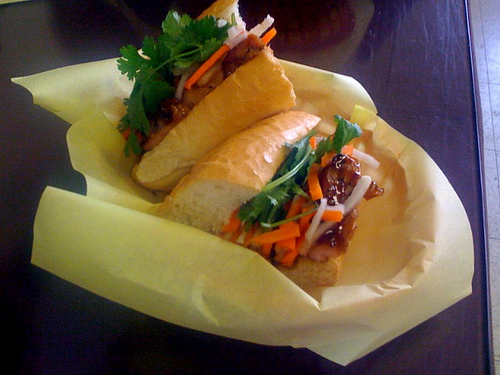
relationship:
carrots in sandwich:
[188, 26, 282, 89] [117, 0, 297, 195]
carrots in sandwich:
[226, 138, 355, 265] [157, 109, 378, 294]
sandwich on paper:
[157, 109, 378, 294] [10, 50, 474, 366]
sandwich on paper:
[117, 0, 297, 195] [10, 50, 474, 366]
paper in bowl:
[10, 50, 474, 366] [122, 84, 440, 319]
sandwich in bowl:
[157, 109, 378, 294] [122, 84, 440, 319]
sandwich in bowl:
[117, 0, 297, 195] [122, 84, 440, 319]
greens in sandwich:
[241, 115, 363, 229] [157, 109, 378, 294]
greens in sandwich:
[115, 8, 231, 151] [117, 0, 297, 195]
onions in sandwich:
[298, 145, 379, 254] [157, 109, 378, 294]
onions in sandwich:
[175, 13, 276, 99] [117, 0, 297, 195]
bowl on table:
[122, 84, 440, 319] [0, 2, 496, 372]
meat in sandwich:
[308, 156, 369, 245] [157, 109, 378, 294]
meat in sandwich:
[139, 35, 263, 147] [117, 0, 297, 195]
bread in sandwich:
[159, 110, 320, 240] [157, 109, 378, 294]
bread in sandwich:
[285, 226, 354, 300] [157, 109, 378, 294]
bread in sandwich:
[132, 48, 296, 200] [117, 0, 297, 195]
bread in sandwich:
[196, 0, 243, 24] [117, 0, 297, 195]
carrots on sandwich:
[188, 26, 282, 89] [117, 0, 297, 195]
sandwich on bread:
[157, 109, 378, 294] [159, 110, 320, 240]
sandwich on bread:
[157, 109, 378, 294] [285, 226, 354, 300]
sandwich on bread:
[117, 0, 297, 195] [132, 48, 296, 200]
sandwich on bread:
[117, 0, 297, 195] [196, 0, 243, 24]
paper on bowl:
[10, 50, 474, 366] [122, 84, 440, 319]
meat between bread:
[308, 156, 369, 245] [285, 226, 354, 300]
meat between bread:
[308, 156, 369, 245] [159, 110, 320, 240]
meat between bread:
[139, 35, 263, 147] [132, 48, 296, 200]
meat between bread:
[139, 35, 263, 147] [196, 0, 243, 24]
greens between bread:
[241, 115, 363, 229] [285, 226, 354, 300]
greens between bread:
[241, 115, 363, 229] [159, 110, 320, 240]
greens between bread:
[115, 8, 231, 151] [132, 48, 296, 200]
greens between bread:
[115, 8, 231, 151] [196, 0, 243, 24]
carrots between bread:
[188, 26, 282, 89] [132, 48, 296, 200]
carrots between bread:
[188, 26, 282, 89] [196, 0, 243, 24]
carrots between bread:
[226, 138, 355, 265] [285, 226, 354, 300]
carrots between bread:
[226, 138, 355, 265] [159, 110, 320, 240]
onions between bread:
[298, 145, 379, 254] [285, 226, 354, 300]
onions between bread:
[298, 145, 379, 254] [159, 110, 320, 240]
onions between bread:
[175, 13, 276, 99] [132, 48, 296, 200]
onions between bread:
[175, 13, 276, 99] [196, 0, 243, 24]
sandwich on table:
[157, 109, 378, 294] [0, 2, 496, 372]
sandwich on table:
[117, 0, 297, 195] [0, 2, 496, 372]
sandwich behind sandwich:
[157, 109, 378, 294] [117, 0, 297, 195]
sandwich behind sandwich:
[117, 0, 297, 195] [157, 109, 378, 294]